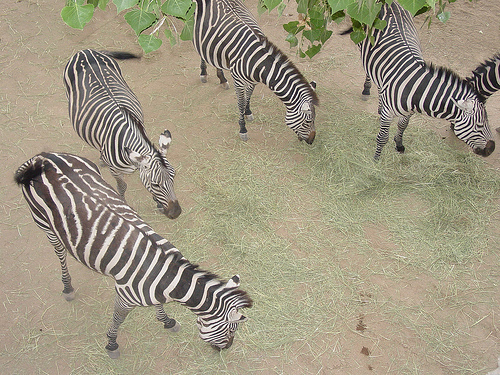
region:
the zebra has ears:
[224, 269, 262, 326]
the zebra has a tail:
[111, 42, 151, 72]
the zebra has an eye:
[145, 176, 164, 191]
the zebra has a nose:
[156, 199, 189, 221]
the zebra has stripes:
[89, 230, 142, 276]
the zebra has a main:
[190, 262, 225, 285]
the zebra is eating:
[183, 5, 328, 151]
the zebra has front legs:
[86, 285, 178, 362]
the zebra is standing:
[45, 39, 250, 218]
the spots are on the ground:
[336, 308, 398, 372]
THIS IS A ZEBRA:
[13, 150, 255, 363]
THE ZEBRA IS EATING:
[12, 146, 255, 357]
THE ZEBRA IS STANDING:
[10, 145, 253, 356]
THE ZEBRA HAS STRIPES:
[12, 150, 253, 363]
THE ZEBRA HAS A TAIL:
[12, 150, 47, 190]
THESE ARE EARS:
[223, 270, 248, 326]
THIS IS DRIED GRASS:
[190, 75, 475, 360]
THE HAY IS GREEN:
[183, 92, 484, 354]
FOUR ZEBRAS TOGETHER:
[8, 6, 499, 353]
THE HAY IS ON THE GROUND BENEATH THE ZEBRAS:
[0, 2, 492, 369]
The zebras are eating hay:
[24, 8, 477, 363]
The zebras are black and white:
[21, 12, 483, 355]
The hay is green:
[190, 118, 468, 340]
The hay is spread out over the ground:
[166, 105, 476, 327]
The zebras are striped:
[187, 28, 477, 192]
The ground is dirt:
[42, 53, 464, 358]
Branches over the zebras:
[58, 1, 448, 58]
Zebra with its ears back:
[428, 64, 498, 169]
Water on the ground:
[343, 293, 388, 359]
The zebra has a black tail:
[11, 153, 80, 207]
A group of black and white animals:
[21, 2, 488, 337]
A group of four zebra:
[13, 3, 495, 350]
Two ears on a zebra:
[117, 121, 178, 164]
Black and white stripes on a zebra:
[61, 176, 182, 296]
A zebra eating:
[235, 30, 346, 168]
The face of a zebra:
[108, 126, 200, 222]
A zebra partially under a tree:
[283, 2, 455, 65]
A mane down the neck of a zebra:
[253, 20, 339, 102]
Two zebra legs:
[90, 302, 185, 361]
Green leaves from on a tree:
[60, 0, 192, 56]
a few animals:
[25, 7, 449, 367]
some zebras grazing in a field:
[32, 12, 472, 370]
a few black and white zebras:
[13, 1, 498, 368]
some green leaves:
[45, 0, 440, 67]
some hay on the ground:
[220, 152, 497, 367]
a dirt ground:
[22, 30, 493, 361]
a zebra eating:
[7, 142, 269, 373]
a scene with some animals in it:
[3, 5, 493, 369]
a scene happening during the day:
[5, 10, 499, 365]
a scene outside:
[9, 12, 496, 373]